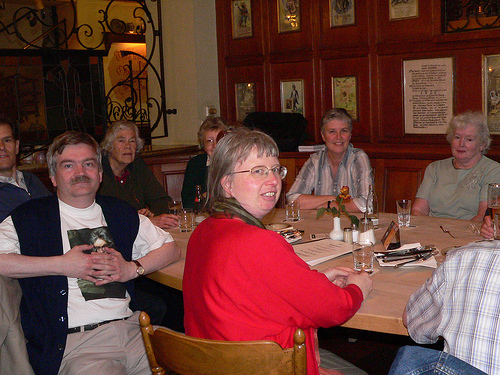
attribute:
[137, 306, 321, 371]
chair — brown, wooden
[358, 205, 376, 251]
shaker — clear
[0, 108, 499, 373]
group — looking forward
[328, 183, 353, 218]
flowers — red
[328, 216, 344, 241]
vase — small and white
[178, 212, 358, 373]
sweater — red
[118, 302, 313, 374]
chair — brown and wooden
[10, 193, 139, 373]
vest — blue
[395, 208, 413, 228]
liquid — clear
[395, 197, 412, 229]
glass — clear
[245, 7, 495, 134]
pictures — framed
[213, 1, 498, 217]
wall — wooden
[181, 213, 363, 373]
shirt — red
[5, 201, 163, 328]
vest — navy blue